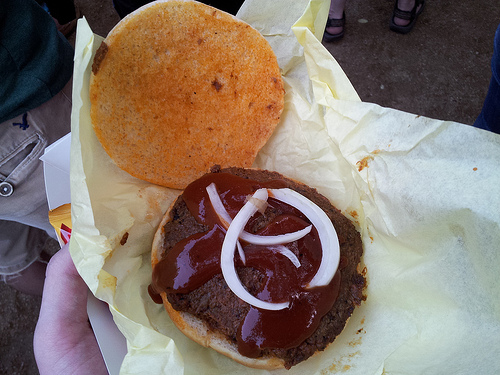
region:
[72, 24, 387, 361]
an opened up sandwich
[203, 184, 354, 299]
slices of onion on sandwich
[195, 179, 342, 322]
onions on top of ketchup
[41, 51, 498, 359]
a white wrapper to sandwich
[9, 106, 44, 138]
a bird symbol on pants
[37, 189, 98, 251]
corner of a chip bag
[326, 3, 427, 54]
the back of someones sandals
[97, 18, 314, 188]
the top bun to burger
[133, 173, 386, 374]
a piece of meat on a bun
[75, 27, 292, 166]
brown bun on paper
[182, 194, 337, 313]
white onions on burger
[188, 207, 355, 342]
burger is dark brown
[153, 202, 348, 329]
burger on toasted bun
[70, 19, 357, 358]
hamburger with barbecue sauce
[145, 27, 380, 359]
hamburger on yellow paper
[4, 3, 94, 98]
person has green shirt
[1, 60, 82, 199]
person has grey shorts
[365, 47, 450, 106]
grey carpet is underfoot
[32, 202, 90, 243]
yellow bag of chips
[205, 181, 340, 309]
Pieces of cut onion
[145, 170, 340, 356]
Sauce on a burger patty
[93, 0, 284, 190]
Top of hamburger bun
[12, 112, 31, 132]
Embroidered American Eagle logo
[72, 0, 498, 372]
Light yellow burger wrapper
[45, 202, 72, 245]
Corner of a chip bag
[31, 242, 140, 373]
Hand holding the food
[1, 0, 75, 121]
Bottom of a green shirt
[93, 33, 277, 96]
Brown colored round cake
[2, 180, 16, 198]
Small white back button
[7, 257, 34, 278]
Small grey colored short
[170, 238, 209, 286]
Thick red tomato sauce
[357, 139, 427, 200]
White soiled paper serviette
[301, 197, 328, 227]
Crisp white circular cheese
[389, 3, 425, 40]
Black leather open shoes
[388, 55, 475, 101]
Rough grey ground floor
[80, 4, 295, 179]
bun is off the burger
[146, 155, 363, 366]
ketchup on the meat patty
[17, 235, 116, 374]
side of the thumb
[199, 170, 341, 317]
onions on the meat patty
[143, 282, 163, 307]
sauce on the paper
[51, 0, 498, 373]
burger on a paper wrapper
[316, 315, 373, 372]
stains on the paper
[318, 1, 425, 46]
sandals on the feet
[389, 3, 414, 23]
thick strap around the back of the foot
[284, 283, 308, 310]
sauce on the onion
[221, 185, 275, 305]
onions atop a burger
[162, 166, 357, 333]
burger patty on a bun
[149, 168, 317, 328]
unidentified red sauce on patty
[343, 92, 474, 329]
yellow paper wrapping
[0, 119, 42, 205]
pocket to a pair of pants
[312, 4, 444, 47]
sandals on a person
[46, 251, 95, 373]
finger holding up the burger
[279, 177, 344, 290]
white onions on a burger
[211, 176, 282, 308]
pearl white onions on a burger